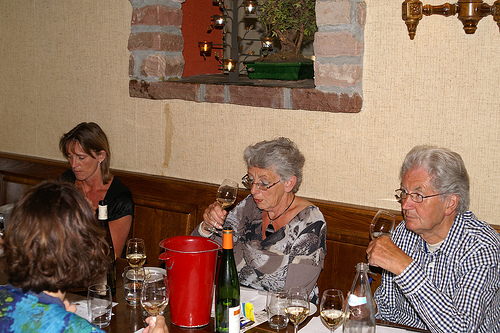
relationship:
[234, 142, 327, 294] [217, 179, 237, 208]
woman drink from a wine glass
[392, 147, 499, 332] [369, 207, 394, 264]
man drinking from a wine glass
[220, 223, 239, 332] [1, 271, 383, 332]
bottle on table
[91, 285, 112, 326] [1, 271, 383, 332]
glass on table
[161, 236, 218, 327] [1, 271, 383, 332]
bucket on table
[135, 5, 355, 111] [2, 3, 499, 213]
brick hole in wall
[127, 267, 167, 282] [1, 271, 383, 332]
plate on table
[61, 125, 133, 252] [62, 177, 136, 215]
woman in black shirt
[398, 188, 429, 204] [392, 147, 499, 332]
glasses on man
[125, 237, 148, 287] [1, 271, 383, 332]
glass on table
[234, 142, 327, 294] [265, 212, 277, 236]
woman wearing necklace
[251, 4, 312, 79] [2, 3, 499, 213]
tree in wall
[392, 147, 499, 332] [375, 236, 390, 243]
man drinking wine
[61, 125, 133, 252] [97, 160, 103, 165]
woman wearing earrings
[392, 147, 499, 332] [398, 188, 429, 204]
man wearing glasses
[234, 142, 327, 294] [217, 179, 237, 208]
woman holding wine glass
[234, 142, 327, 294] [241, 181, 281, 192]
woman wearing glasses